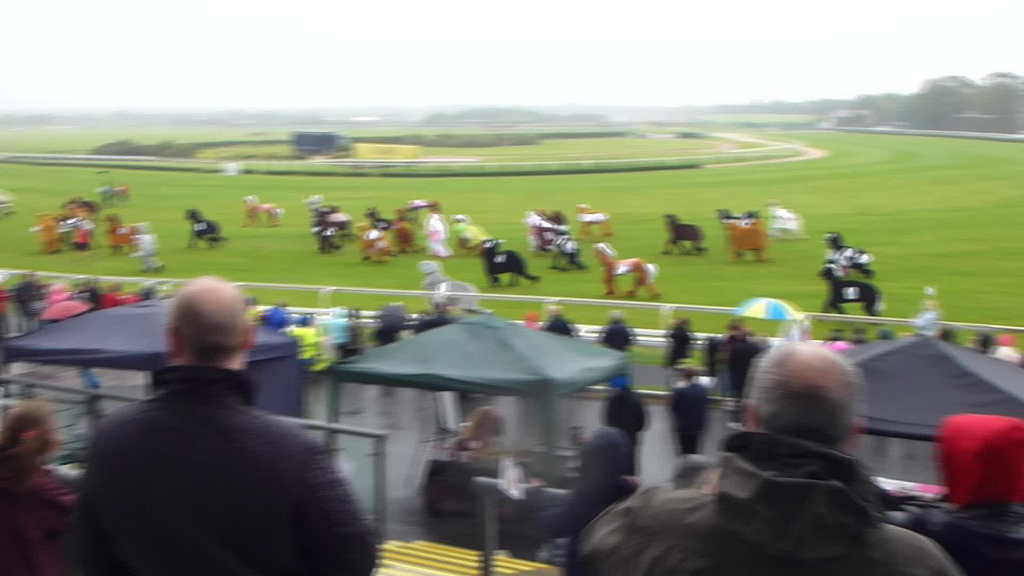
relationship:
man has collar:
[75, 278, 387, 574] [140, 361, 261, 400]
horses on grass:
[125, 178, 739, 285] [148, 173, 902, 331]